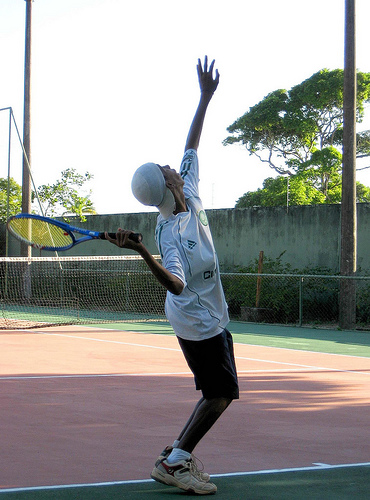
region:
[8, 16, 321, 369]
a man playing tennis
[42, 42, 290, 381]
a man with an arm extended in the air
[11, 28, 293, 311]
a man with an arm in the air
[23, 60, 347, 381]
a man wearing a hat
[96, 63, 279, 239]
a man wearing a white hat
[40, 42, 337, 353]
a man wearing a shirt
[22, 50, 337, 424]
a man wearing a white shirt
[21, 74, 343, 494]
a man wearing shorts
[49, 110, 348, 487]
a man wearing black shorts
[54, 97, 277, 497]
a man on a tennis court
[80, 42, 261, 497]
a tennis player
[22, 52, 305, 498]
a person on a tennis court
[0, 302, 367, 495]
a red tennis court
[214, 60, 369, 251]
a green tree in the background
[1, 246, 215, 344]
a white net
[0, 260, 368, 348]
a fence in the distance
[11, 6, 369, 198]
a sky that is white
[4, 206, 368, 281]
a concrete wall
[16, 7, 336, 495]
a scene outside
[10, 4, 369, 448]
a scene happening during the day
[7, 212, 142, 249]
blue and yellow tennis racquet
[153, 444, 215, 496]
tan and brown sneakers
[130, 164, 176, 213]
white backwards baseball cap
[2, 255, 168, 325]
white tennis net on court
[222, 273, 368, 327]
metal chain link fence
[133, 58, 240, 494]
man playing tennis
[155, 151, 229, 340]
black and white shirt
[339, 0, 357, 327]
brown wooden electrical pole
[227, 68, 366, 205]
tree next to tennis court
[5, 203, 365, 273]
grey stone barrier wall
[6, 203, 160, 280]
He's holding an object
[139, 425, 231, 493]
white shoes on the floor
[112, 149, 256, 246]
Caucasian man on field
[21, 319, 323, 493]
This is a tennis court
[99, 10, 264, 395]
He threw the ball into the air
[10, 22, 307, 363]
He is about to hit the ball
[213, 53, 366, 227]
Tree behind the fence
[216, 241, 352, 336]
Bushes beside the metal gate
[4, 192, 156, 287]
This racket is blue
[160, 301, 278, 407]
The guy is wearing black shorts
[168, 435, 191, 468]
bright white socks on man's feet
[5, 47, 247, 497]
tennis player preparing to serve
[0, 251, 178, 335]
tennis court net behind man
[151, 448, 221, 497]
tan, black, grey and red sneakers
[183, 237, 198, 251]
Addidas logo on man's shirt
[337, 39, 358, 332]
light pole behind fencing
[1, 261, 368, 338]
chain link fence around tennis court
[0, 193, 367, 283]
concrete retaining wall behind fence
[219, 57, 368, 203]
tall tree behind concrete wall